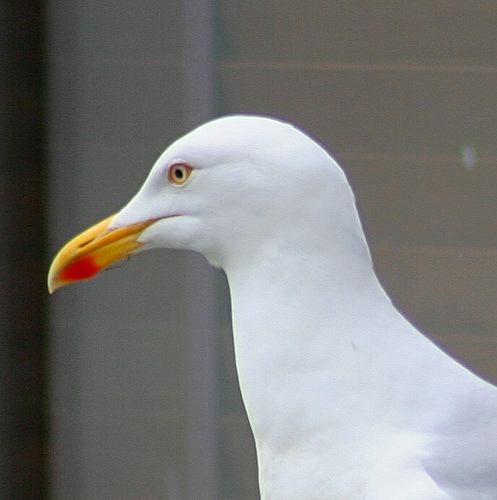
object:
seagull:
[44, 112, 497, 500]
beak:
[47, 212, 182, 294]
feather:
[387, 446, 421, 471]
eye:
[165, 159, 194, 186]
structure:
[0, 0, 225, 500]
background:
[3, 0, 151, 159]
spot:
[59, 256, 100, 284]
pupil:
[175, 169, 183, 178]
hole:
[77, 238, 96, 248]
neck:
[225, 222, 383, 358]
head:
[45, 112, 363, 297]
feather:
[278, 454, 340, 496]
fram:
[184, 0, 218, 134]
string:
[106, 256, 130, 270]